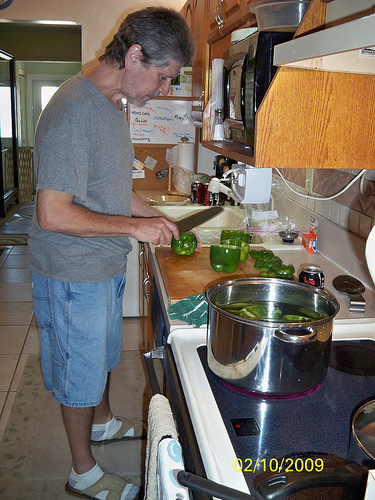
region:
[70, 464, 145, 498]
sock on right foot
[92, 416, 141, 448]
sock on left foot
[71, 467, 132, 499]
sandal on right foot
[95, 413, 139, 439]
sandal on left foot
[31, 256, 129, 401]
jean shorts are blue in color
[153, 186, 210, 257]
person holding knife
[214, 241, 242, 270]
top of bell pepper is missing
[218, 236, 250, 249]
top of bell pepper is missing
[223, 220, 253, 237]
top of bell pepper is missing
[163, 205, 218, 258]
man cutting a green pepper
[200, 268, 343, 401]
pot on top of the stove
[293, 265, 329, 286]
soda can on the stove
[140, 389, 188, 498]
towel on the stove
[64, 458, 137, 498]
man wearing white and grey socks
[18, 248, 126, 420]
man wearing blue jeans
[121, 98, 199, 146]
writing on a chalkboard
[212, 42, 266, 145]
microwave on the shelf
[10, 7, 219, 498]
this is a man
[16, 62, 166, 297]
man wearing a grey shirt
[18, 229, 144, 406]
man wearing blue jean shorts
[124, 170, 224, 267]
man holding a knife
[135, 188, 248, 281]
the man is cutting a bell pepper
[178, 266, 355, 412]
this is a pot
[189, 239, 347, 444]
the pot on a burner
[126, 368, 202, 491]
towel hanging on door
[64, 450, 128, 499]
man wearing white socks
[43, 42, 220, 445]
a man cutting a pepper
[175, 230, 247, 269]
a green pepper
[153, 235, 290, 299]
the cutting board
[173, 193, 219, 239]
the knife the man is holding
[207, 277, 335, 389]
a pot on the stove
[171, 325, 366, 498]
the stove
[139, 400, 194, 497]
towels hanging from the stove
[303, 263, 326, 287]
a can on the counter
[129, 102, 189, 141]
a white board on the wall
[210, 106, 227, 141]
a salt shaker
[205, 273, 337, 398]
Silver pot on top of stove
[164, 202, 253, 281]
Green peppers on cutting board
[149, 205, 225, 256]
Man cutting green pepper with silver knife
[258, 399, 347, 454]
Blue top stove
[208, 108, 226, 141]
Clear salt shaker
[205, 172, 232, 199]
White kitchen faucet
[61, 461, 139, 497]
Tan sandles with white and gray socks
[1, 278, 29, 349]
Beige tile on floor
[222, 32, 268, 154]
Black microwave on wooden shelf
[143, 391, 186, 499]
Two towels hanging on front of stove